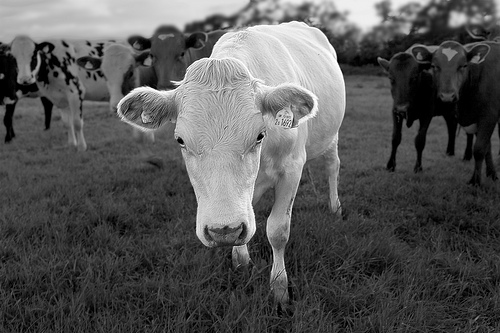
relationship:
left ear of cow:
[264, 83, 317, 128] [119, 22, 347, 310]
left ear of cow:
[467, 44, 489, 65] [412, 38, 498, 181]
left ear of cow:
[187, 31, 209, 51] [131, 25, 209, 62]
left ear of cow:
[37, 42, 56, 55] [5, 33, 120, 150]